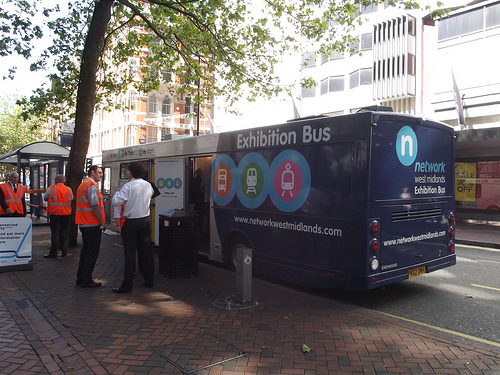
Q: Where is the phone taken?
A: On the sidewalk.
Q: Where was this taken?
A: Street.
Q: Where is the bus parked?
A: Side of the street.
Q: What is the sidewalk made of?
A: Brick.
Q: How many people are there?
A: 5.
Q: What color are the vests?
A: Orange.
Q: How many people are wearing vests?
A: 3.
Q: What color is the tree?
A: Green.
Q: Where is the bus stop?
A: Behind the bus.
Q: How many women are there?
A: 0.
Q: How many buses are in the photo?
A: One.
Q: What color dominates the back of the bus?
A: Black.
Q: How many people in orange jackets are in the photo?
A: Three.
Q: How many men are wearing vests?
A: Three.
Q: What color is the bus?
A: Blue and white.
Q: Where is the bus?
A: On the side of the road.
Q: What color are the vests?
A: Orange.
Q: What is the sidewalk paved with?
A: Bricks.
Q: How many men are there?
A: Four.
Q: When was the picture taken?
A: Daytime.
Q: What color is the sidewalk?
A: Red.